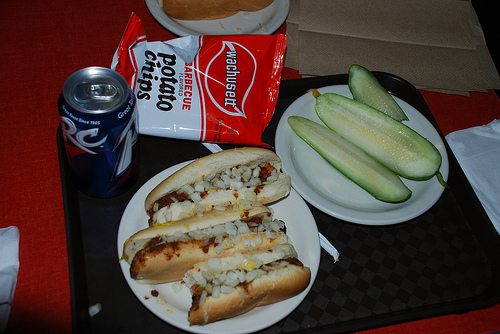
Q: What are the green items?
A: Pickles.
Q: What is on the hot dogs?
A: Chili.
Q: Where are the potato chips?
A: Between the cola and the pickles.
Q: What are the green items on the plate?
A: Pickles.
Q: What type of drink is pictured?
A: Soda.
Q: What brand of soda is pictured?
A: RC.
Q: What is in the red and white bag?
A: Potato chips.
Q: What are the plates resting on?
A: Cafeteria tray.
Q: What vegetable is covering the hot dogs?
A: Onion.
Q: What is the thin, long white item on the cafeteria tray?
A: Straw.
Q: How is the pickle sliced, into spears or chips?
A: Spears.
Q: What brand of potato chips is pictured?
A: Wachusett.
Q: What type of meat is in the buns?
A: Hot dogs.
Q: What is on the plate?
A: Pickles.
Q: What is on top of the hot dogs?
A: Onions.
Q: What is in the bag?
A: Chips.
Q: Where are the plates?
A: On a table.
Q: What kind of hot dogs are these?
A: Chili dogs.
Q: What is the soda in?
A: A can.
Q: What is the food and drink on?
A: Tray.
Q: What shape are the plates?
A: Round.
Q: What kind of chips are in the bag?
A: Potato chips.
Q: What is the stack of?
A: Paper towels.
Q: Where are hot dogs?
A: On a plate.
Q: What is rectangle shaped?
A: The tray.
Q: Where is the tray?
A: On a table.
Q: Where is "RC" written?
A: On soda can.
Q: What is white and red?
A: Potato chip bag.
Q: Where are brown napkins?
A: On a table.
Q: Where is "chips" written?
A: On potato chip bag.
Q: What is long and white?
A: A straw.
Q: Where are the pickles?
A: On plate.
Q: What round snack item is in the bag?
A: Chips.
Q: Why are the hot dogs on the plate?
A: To eat.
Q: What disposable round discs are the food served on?
A: Paper plates.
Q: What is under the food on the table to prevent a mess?
A: Mat.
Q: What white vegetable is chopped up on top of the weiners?
A: Onion.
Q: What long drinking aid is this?
A: Straw.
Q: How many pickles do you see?
A: Three.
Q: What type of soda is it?
A: RC.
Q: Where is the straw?
A: Under the hot dog plate.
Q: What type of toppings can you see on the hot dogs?
A: Chili and onions.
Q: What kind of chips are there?
A: Barbecue.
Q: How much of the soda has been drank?
A: None.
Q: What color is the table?
A: Red.